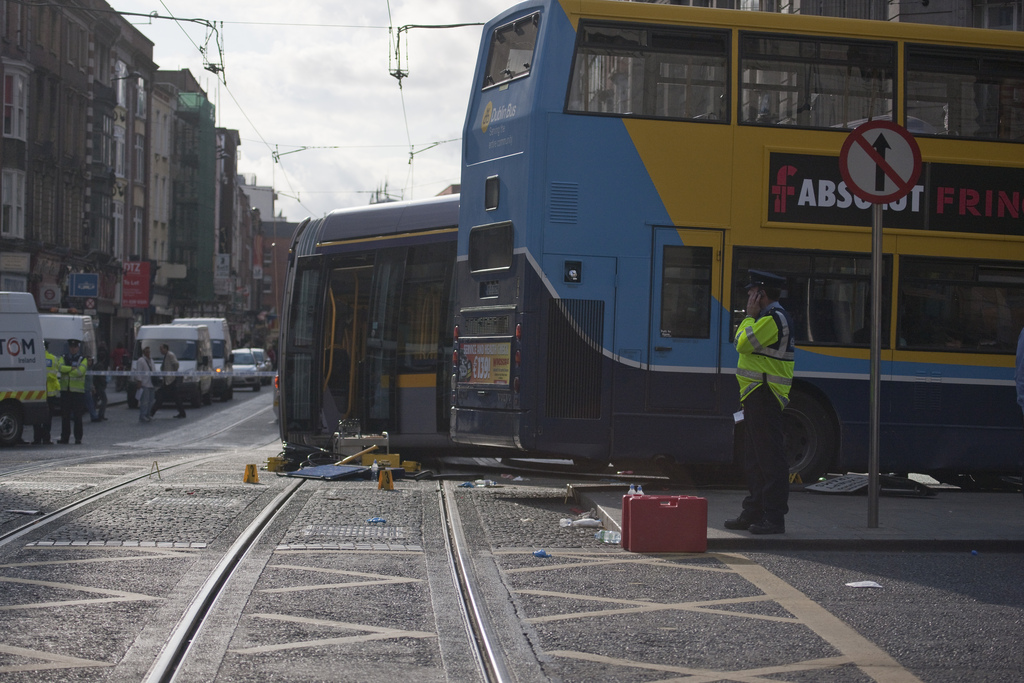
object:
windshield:
[228, 355, 263, 366]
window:
[477, 11, 542, 85]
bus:
[471, 77, 1022, 482]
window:
[559, 19, 1019, 157]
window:
[640, 210, 1021, 387]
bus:
[266, 199, 929, 466]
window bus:
[569, 11, 731, 142]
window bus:
[733, 23, 905, 122]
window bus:
[906, 33, 1019, 132]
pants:
[733, 379, 794, 510]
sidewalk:
[573, 478, 1022, 552]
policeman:
[725, 263, 801, 532]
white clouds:
[118, 0, 528, 220]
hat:
[744, 257, 798, 297]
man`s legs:
[725, 381, 793, 534]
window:
[740, 246, 891, 357]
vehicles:
[139, 313, 260, 394]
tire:
[246, 373, 273, 394]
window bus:
[562, 36, 642, 120]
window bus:
[774, 245, 889, 341]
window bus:
[884, 260, 1023, 368]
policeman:
[722, 268, 818, 524]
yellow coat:
[725, 319, 804, 402]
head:
[706, 266, 796, 334]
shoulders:
[750, 311, 785, 341]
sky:
[0, 3, 1024, 243]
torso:
[733, 355, 790, 405]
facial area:
[736, 280, 758, 312]